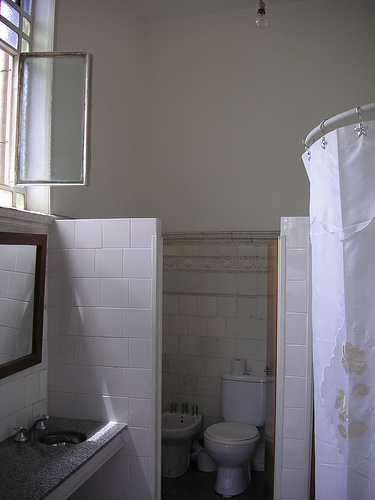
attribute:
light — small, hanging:
[250, 2, 272, 35]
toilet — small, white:
[204, 358, 266, 496]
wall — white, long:
[50, 4, 373, 475]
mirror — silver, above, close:
[1, 235, 51, 376]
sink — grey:
[3, 410, 121, 500]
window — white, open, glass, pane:
[0, 12, 90, 198]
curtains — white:
[307, 104, 371, 496]